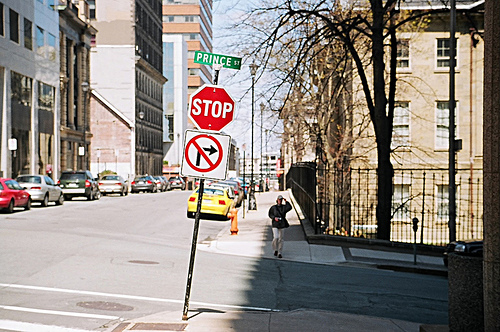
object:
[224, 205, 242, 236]
fire hydrant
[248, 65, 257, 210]
pole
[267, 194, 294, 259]
pedestrian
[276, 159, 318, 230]
fence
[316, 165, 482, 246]
fence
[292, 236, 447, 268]
sidewalk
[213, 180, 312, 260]
sidewalk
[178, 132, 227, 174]
turn sign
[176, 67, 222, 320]
leaning pole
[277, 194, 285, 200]
hat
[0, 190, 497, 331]
street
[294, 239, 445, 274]
curb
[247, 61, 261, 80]
light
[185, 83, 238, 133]
sign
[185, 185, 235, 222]
car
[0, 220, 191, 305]
intersection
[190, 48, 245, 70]
sign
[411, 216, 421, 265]
meter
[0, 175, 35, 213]
car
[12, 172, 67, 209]
car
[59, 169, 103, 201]
car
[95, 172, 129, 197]
car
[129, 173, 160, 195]
car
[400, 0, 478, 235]
tree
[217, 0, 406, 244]
tree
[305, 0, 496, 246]
building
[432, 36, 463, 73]
window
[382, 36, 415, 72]
window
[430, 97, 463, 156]
window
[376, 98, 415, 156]
window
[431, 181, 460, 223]
window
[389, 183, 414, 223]
window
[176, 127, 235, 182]
sign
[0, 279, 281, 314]
line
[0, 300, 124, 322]
line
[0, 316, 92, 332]
line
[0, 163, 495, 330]
ground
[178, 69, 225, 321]
pole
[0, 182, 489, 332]
asphalt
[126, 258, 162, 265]
drain cover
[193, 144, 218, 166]
right turns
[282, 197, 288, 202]
hand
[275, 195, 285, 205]
head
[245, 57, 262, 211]
street light